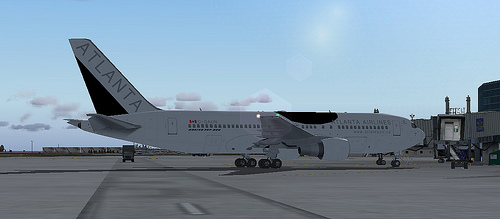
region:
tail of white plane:
[58, 27, 162, 118]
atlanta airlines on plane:
[334, 114, 399, 129]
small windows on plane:
[186, 118, 261, 134]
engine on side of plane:
[292, 132, 359, 169]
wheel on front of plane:
[383, 156, 412, 176]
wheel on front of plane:
[370, 158, 386, 170]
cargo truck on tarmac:
[114, 142, 144, 167]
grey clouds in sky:
[8, 84, 60, 140]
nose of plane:
[404, 116, 430, 153]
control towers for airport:
[436, 88, 473, 114]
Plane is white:
[62, 31, 427, 178]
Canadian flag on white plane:
[187, 114, 197, 126]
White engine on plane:
[316, 134, 356, 161]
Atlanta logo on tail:
[75, 40, 147, 119]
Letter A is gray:
[76, 40, 91, 54]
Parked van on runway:
[120, 142, 138, 165]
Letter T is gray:
[84, 47, 101, 64]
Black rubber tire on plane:
[262, 155, 272, 166]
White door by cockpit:
[392, 117, 402, 139]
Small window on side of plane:
[185, 121, 194, 129]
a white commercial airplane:
[42, 27, 439, 179]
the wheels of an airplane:
[223, 155, 288, 173]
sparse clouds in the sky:
[0, 87, 80, 137]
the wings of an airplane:
[248, 105, 324, 157]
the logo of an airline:
[62, 22, 159, 118]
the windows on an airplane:
[184, 113, 249, 136]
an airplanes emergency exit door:
[163, 112, 188, 143]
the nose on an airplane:
[360, 102, 430, 153]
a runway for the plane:
[76, 167, 258, 215]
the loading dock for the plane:
[414, 106, 496, 178]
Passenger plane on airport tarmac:
[53, 30, 435, 180]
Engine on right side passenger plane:
[295, 131, 361, 172]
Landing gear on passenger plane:
[218, 151, 296, 178]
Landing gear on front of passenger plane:
[357, 147, 412, 173]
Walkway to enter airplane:
[432, 108, 497, 151]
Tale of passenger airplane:
[59, 28, 169, 157]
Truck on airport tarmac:
[95, 131, 157, 173]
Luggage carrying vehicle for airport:
[435, 133, 487, 173]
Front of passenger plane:
[372, 104, 439, 166]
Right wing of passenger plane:
[251, 106, 328, 150]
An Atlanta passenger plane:
[63, 36, 423, 168]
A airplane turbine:
[297, 135, 352, 161]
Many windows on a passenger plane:
[186, 122, 388, 129]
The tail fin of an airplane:
[68, 38, 163, 115]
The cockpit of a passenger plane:
[407, 118, 416, 127]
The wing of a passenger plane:
[255, 115, 329, 148]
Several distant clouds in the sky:
[0, 92, 272, 132]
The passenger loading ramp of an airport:
[435, 112, 499, 142]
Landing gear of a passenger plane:
[233, 151, 400, 169]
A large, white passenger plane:
[61, 37, 424, 167]